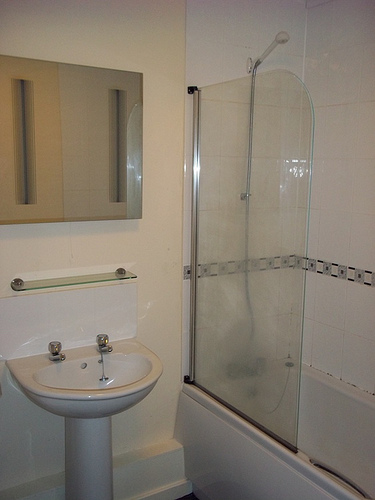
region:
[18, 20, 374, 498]
the scene is in a bathroom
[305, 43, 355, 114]
the wall is tiled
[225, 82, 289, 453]
the door is made of glass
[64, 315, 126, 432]
the sink is white in colour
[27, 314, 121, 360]
the taps are silver in colour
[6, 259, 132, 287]
a glass is on the shelf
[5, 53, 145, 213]
the cupboard is brown in colour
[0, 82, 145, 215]
the cupboard is wooden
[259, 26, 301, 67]
the shower is white in colour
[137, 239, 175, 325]
the wall is brown in colour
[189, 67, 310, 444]
clear glass wall of the shower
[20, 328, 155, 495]
white porcelain sink in the bathroom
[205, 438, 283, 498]
white side of the bathtup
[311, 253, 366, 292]
grey and black trim of the wall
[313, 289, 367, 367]
white tile surface of the wall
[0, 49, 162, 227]
square mirror mounted on the wall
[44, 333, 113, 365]
grey metal knobs of the sink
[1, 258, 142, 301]
glass shelf attached to the wall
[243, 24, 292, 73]
white shower head attached to the wall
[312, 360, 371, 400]
black mold growing on the base of the wall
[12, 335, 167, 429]
White sink in the bathroom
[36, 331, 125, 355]
Faucet on the sink.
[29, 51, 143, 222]
Mirror on the wall.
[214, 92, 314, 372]
Shower glass door on the tub.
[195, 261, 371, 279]
Black and white tile around the shower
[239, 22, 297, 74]
Shower head in the shower.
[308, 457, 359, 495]
Track of the shower door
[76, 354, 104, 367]
Two holes in the sink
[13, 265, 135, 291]
Glass shelf above the sink.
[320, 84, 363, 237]
White tile on the shower.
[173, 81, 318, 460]
clear glass on shower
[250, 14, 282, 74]
white head on shower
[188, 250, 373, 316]
black and white tile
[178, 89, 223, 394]
metal bar on door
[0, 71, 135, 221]
metal doors above sink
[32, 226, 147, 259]
white wall in bathroom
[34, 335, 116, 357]
metal handles on sink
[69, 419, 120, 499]
white base on sink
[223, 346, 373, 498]
white tub in shower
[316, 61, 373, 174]
white tile on wall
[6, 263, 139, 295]
the clear shelf over the sink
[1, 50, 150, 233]
the mirror above the bathroom sink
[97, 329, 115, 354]
the faucet for the sink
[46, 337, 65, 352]
the knob for the sink faucet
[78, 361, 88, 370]
the hole in the bowl of the sink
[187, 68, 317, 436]
the glass door on the bathtub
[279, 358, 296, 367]
the plug for the drain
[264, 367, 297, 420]
the chain for the bathtub plug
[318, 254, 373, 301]
the desgins on the tile wall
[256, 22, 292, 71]
the white shower head in the bathtub